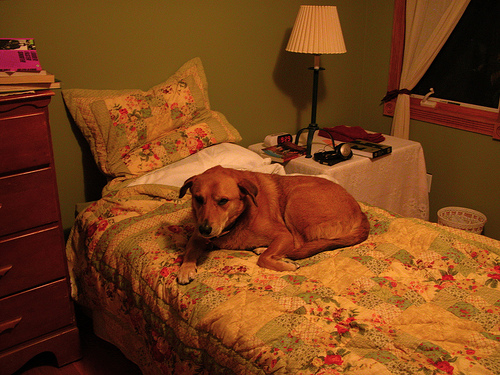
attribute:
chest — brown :
[1, 85, 89, 374]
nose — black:
[199, 220, 213, 237]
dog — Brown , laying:
[166, 161, 371, 292]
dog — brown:
[153, 157, 381, 276]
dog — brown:
[177, 163, 370, 284]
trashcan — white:
[430, 205, 498, 247]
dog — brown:
[165, 163, 374, 275]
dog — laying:
[176, 164, 370, 271]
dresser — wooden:
[7, 79, 77, 371]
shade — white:
[278, 2, 369, 62]